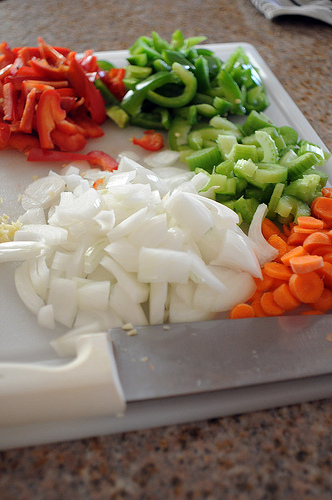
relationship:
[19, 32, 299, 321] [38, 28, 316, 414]
food on board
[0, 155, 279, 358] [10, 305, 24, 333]
onion on board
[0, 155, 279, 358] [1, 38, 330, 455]
onion on cutting board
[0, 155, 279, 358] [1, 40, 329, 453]
onion on board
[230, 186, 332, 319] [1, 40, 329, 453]
carrot on board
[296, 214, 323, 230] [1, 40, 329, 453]
carrot on board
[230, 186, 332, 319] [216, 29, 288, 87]
carrot on cutting board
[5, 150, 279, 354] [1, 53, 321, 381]
onion on plate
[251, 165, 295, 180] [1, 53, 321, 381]
celery on plate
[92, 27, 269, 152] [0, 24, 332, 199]
green peppers on plate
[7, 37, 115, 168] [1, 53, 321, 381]
peppers on plate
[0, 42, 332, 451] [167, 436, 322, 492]
board on counter top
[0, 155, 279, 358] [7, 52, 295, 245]
onion on top of cutting board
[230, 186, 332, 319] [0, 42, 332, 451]
carrot on top of board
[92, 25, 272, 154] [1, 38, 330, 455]
green peppers on top of cutting board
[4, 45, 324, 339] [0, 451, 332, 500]
board on top of counter top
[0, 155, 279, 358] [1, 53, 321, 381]
onion on plate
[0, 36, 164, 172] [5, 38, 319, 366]
peppers on cutting board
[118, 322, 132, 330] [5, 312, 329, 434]
crumb on knife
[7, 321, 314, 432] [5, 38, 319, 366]
knife on cutting board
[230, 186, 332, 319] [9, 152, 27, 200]
carrot on plate